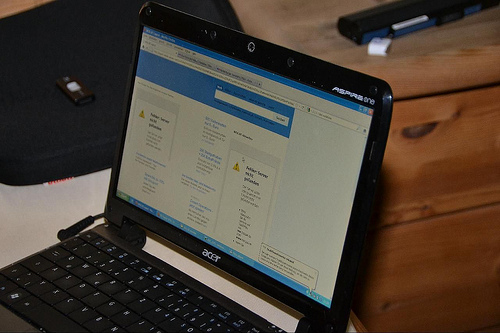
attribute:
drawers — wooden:
[242, 15, 497, 331]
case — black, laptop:
[2, 0, 254, 192]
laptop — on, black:
[0, 2, 393, 331]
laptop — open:
[72, 9, 379, 315]